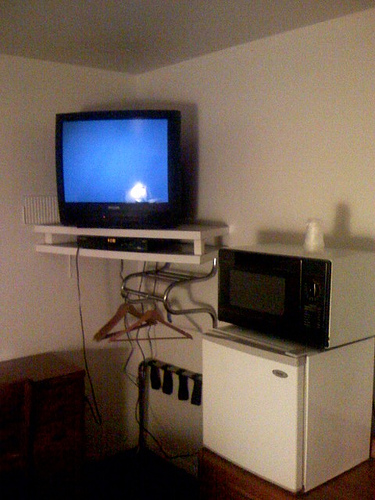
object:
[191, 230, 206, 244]
corner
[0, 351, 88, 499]
desk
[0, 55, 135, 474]
wall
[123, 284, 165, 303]
bar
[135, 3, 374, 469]
wall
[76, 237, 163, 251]
dvd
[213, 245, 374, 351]
microwave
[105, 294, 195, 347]
hanger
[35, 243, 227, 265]
shelf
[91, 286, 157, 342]
hanger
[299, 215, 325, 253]
plastic cups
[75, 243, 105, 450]
cord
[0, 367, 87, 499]
chair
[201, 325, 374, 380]
refrigerator top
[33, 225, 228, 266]
stand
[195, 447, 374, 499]
table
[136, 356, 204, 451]
bar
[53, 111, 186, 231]
television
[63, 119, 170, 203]
screen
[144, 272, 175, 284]
rack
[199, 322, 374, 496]
mini fridge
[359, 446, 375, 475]
corner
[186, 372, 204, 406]
strap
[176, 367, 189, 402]
strap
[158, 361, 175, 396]
strap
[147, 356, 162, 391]
strap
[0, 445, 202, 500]
mat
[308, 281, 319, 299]
knob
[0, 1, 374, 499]
room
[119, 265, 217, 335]
rail